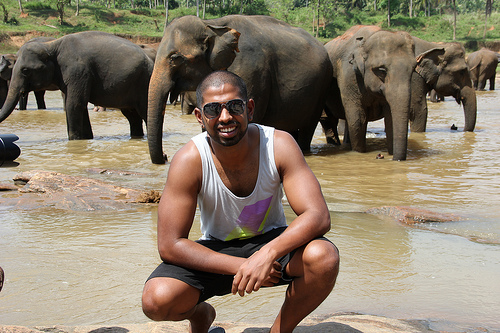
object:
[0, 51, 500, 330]
lake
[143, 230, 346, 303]
shorts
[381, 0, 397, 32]
tree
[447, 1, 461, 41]
tree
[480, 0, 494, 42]
tree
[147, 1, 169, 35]
tree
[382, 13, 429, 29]
leaves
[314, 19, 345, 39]
leaves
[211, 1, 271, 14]
leaves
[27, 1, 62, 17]
leaves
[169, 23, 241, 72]
ear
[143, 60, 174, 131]
dirt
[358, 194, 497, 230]
rocks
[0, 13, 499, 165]
animals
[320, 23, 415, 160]
elephant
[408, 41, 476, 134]
elephant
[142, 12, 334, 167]
elephant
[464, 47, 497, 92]
elephant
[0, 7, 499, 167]
herd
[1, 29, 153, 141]
elephant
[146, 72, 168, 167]
trunk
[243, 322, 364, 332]
shadow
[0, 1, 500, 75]
ground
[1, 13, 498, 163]
monitor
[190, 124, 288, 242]
vest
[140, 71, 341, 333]
man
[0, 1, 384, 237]
picture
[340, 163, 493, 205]
ripples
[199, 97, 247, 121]
sunglasses